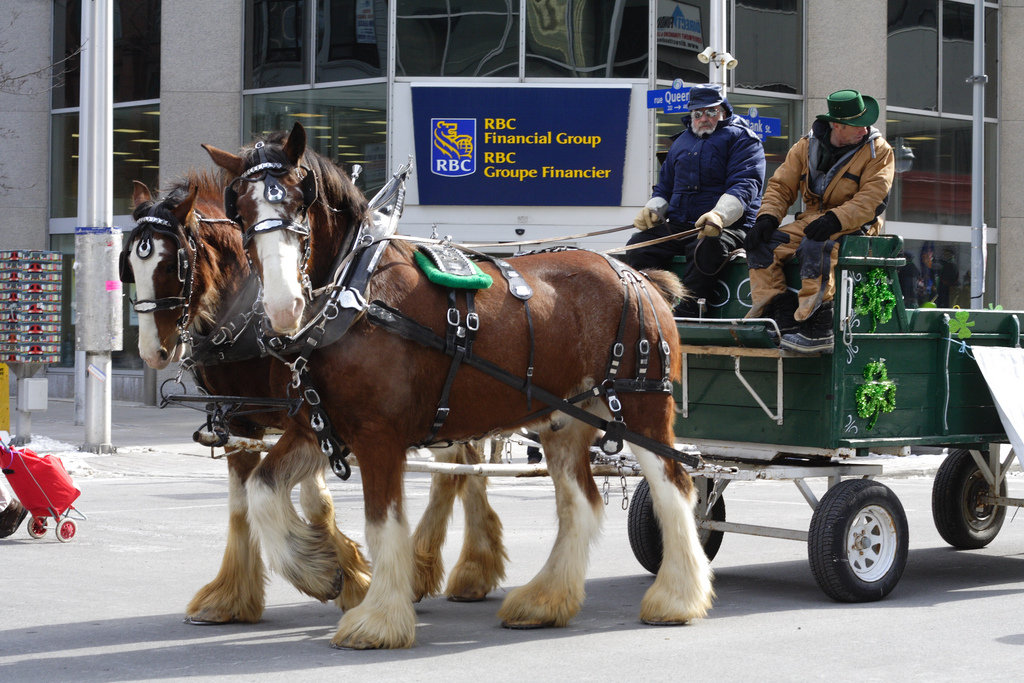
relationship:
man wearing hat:
[610, 67, 757, 281] [675, 87, 732, 120]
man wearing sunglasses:
[625, 84, 767, 317] [677, 106, 734, 119]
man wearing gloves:
[625, 84, 767, 317] [627, 193, 748, 233]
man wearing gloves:
[753, 89, 903, 366] [753, 210, 836, 254]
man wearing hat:
[744, 89, 895, 354] [828, 83, 883, 136]